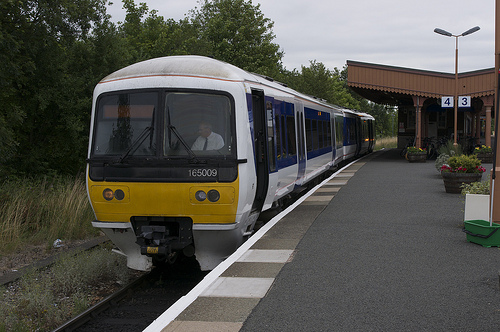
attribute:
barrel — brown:
[441, 172, 482, 189]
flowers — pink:
[440, 162, 483, 172]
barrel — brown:
[406, 152, 427, 159]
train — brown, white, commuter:
[80, 52, 380, 275]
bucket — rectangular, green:
[461, 217, 498, 247]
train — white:
[72, 50, 340, 264]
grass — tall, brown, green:
[2, 178, 89, 241]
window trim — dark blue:
[265, 100, 330, 168]